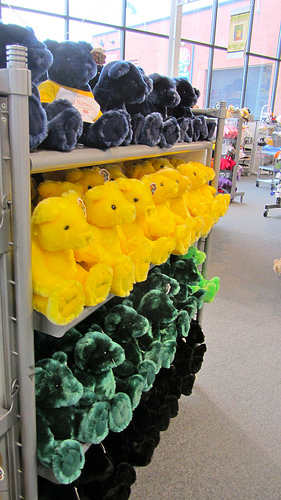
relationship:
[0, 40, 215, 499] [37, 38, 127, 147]
shelf full of bear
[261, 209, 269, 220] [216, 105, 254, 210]
wheel on rack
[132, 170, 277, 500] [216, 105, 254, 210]
floor by rack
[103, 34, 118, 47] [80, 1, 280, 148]
light on building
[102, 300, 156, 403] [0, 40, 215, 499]
stuffed animal on shelf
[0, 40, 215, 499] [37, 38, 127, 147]
shelf with a bear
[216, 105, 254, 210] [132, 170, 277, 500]
rack on floor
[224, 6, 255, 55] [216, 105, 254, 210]
banner by rack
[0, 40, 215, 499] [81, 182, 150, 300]
shelf with teddy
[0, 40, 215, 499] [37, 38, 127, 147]
shelf with bear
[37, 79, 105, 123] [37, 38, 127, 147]
shirt on bear